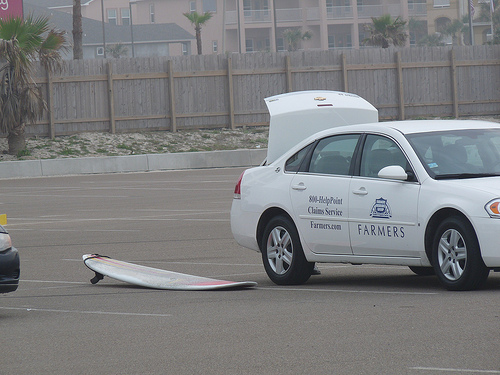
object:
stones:
[0, 125, 267, 162]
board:
[80, 252, 258, 291]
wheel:
[258, 212, 315, 287]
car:
[229, 90, 499, 291]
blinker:
[233, 168, 245, 199]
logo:
[367, 195, 392, 220]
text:
[354, 224, 406, 240]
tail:
[228, 165, 264, 251]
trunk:
[228, 90, 499, 292]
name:
[355, 223, 405, 239]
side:
[227, 128, 499, 291]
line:
[0, 304, 172, 318]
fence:
[0, 44, 499, 140]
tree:
[0, 10, 71, 155]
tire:
[425, 215, 492, 292]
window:
[245, 37, 254, 53]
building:
[0, 0, 195, 62]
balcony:
[224, 9, 319, 30]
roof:
[23, 3, 198, 46]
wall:
[28, 43, 170, 61]